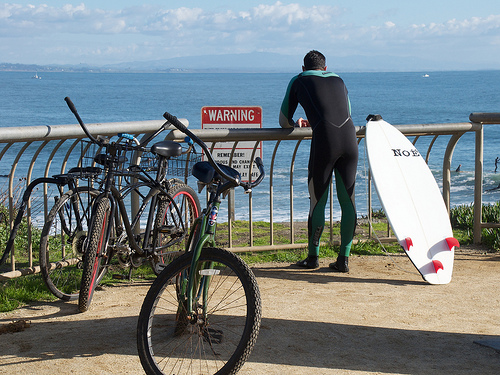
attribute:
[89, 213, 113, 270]
wheel — red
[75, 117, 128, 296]
bike — black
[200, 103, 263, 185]
warning sign — red, white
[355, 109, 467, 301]
surfboard — white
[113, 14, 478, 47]
sky — blue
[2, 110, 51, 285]
rack — metal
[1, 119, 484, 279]
rail — metal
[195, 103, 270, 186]
sign — red, white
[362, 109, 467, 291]
surfboard — white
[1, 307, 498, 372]
shadow — long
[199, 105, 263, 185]
sign — white, red, warning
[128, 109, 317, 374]
bike — green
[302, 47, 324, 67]
hair — black, short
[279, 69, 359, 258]
wetsuit — black, teal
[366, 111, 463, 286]
surfboard — white, red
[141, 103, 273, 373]
bicycle — black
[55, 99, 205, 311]
bicycle — black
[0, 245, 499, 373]
ground — dirt, dry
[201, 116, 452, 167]
railng — silver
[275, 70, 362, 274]
wetsuit — black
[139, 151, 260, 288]
bike — green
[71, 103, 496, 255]
railing — gray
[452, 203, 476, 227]
area — grassy, small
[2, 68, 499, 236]
ocean — blue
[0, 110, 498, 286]
fence — metal, gray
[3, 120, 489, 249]
railing — gray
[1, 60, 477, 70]
shore — distant